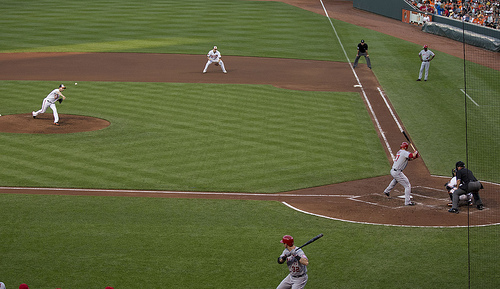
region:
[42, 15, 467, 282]
the people are playing baseball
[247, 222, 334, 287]
the team at bat are in grey & red uniforms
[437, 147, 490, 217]
the umpire is wearing grey trousers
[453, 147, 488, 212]
the umpire is wearing a black shirt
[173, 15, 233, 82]
the team on the field is wearing white uniforms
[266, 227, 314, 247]
the on deck batter has a red helmet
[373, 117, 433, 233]
this player is about to swing his bat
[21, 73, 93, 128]
the pitcher has just released the ball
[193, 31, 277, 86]
the first baseman is really too far off the base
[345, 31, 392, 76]
the first base ump has his hands resting on his knees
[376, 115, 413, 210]
The batter has a black and brown bat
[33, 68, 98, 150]
The pitcher throws a ball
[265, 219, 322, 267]
The man is wearing a red helmet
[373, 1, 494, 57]
People sit in the stands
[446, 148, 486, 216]
The umpire crouches on the base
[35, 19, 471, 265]
The field is dirt and grass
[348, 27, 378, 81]
The man is wearing all black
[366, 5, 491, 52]
The sides of the stadium are green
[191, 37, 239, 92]
The man has a mitt on his hand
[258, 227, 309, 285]
The mans uniform is white and red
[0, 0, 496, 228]
a baseball diamond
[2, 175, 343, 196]
a white line on a baseball field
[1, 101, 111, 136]
a pitcher's mound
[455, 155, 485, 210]
an umpire in black and grey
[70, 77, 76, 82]
a ball flying through the air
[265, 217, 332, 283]
a man warming up his batting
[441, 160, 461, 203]
a catcher in front of an umpire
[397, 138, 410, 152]
a red helmet on a batter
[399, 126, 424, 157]
a bat in a batter's hands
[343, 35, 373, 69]
a referee waitin behind first base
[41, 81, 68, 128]
Pitcher throwing a baseball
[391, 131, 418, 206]
Batter swinging bat at ball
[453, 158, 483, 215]
Umpire reffing baseball game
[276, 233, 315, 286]
Player practicing swinging bat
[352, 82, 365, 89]
Empty white first base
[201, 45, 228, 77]
First baseman preparing to catch ball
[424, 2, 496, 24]
Crowd watching baseball game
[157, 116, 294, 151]
Beautiful green baseball turf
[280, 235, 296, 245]
Red safety helmet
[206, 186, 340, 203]
Long white chalk line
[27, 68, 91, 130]
the pitch is away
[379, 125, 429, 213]
right handed batting stance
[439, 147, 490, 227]
the umpire is watchful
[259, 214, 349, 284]
on deck hitter taking practice swing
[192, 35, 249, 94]
first baseman is ready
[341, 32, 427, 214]
first base umpire on the line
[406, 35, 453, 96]
first base coach hands on hips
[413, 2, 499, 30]
small section of crowd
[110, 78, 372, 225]
artificial turf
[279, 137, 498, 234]
the batting circle